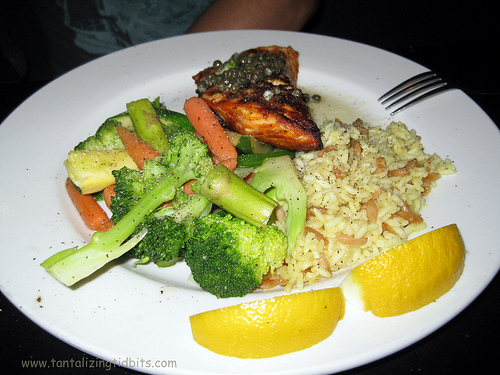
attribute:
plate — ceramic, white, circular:
[9, 18, 494, 328]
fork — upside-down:
[367, 52, 463, 131]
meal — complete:
[41, 44, 466, 363]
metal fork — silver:
[364, 58, 492, 125]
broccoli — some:
[67, 77, 305, 279]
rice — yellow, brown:
[260, 113, 459, 288]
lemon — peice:
[157, 219, 468, 366]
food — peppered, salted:
[97, 59, 402, 292]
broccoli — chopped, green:
[81, 80, 295, 273]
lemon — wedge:
[329, 218, 464, 314]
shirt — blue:
[48, 0, 220, 56]